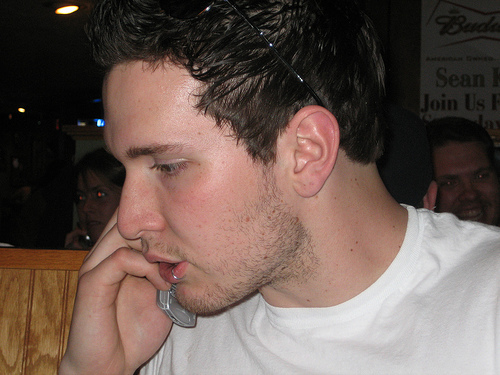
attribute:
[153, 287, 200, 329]
cellphone — small, grey, old, silver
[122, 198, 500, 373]
t-shirt — white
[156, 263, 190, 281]
lip — pierced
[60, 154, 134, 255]
woman — smoking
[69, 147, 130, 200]
hair — brown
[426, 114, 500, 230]
man — smiling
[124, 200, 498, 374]
shirt — white, cotton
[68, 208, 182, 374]
hand — right one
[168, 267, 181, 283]
ring — silver, metal, round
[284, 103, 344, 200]
ear — pink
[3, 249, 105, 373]
booth — wooden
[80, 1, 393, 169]
hair — dark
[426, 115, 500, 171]
hair — dark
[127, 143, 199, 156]
eyebrow — dark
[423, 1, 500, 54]
budweiser — advertising, an advertisement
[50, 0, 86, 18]
ceiling light — bright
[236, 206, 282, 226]
freckles — brown, small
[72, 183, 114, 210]
eyes — red